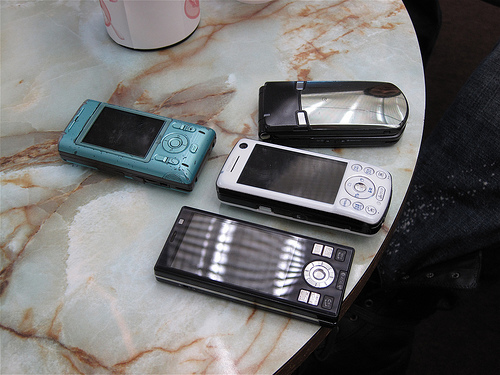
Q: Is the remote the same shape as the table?
A: Yes, both the remote and the table are round.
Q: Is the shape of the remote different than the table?
A: No, both the remote and the table are round.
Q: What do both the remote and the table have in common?
A: The shape, both the remote and the table are round.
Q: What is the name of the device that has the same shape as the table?
A: The device is a remote control.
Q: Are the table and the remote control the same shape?
A: Yes, both the table and the remote control are round.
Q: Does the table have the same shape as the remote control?
A: Yes, both the table and the remote control are round.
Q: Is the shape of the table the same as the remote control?
A: Yes, both the table and the remote control are round.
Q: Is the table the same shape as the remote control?
A: Yes, both the table and the remote control are round.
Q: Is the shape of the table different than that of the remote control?
A: No, both the table and the remote control are round.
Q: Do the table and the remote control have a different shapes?
A: No, both the table and the remote control are round.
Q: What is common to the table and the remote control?
A: The shape, both the table and the remote control are round.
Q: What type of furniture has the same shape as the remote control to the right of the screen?
A: The table is the same shape as the remote.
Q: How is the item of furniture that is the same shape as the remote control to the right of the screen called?
A: The piece of furniture is a table.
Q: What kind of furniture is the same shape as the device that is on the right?
A: The table is the same shape as the remote.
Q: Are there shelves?
A: No, there are no shelves.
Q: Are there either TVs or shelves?
A: No, there are no shelves or tvs.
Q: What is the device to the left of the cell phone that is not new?
A: The device is a screen.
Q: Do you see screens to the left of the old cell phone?
A: Yes, there is a screen to the left of the cellphone.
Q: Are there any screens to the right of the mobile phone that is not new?
A: No, the screen is to the left of the cell phone.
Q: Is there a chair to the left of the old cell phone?
A: No, there is a screen to the left of the cellphone.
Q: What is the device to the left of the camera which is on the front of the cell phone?
A: The device is a screen.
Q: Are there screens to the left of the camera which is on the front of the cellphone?
A: Yes, there is a screen to the left of the camera.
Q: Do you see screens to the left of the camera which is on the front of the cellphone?
A: Yes, there is a screen to the left of the camera.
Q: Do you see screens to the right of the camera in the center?
A: No, the screen is to the left of the camera.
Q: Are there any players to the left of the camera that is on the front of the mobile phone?
A: No, there is a screen to the left of the camera.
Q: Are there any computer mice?
A: No, there are no computer mice.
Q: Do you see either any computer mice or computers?
A: No, there are no computer mice or computers.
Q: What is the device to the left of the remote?
A: The device is a screen.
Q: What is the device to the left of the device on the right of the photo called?
A: The device is a screen.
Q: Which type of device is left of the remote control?
A: The device is a screen.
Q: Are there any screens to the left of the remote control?
A: Yes, there is a screen to the left of the remote control.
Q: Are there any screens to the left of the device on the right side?
A: Yes, there is a screen to the left of the remote control.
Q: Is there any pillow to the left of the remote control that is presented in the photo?
A: No, there is a screen to the left of the remote control.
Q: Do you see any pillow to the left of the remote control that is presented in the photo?
A: No, there is a screen to the left of the remote control.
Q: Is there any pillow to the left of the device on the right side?
A: No, there is a screen to the left of the remote control.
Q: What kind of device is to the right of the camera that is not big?
A: The device is a screen.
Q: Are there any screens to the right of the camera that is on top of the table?
A: Yes, there is a screen to the right of the camera.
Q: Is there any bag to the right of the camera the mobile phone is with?
A: No, there is a screen to the right of the camera.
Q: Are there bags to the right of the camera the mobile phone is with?
A: No, there is a screen to the right of the camera.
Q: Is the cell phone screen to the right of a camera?
A: Yes, the screen is to the right of a camera.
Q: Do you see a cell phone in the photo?
A: Yes, there is a cell phone.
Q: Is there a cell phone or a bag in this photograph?
A: Yes, there is a cell phone.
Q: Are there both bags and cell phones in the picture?
A: No, there is a cell phone but no bags.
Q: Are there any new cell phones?
A: Yes, there is a new cell phone.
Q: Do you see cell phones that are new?
A: Yes, there is a cell phone that is new.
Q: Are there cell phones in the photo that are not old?
A: Yes, there is an new cell phone.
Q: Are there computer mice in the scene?
A: No, there are no computer mice.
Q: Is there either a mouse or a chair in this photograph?
A: No, there are no computer mice or chairs.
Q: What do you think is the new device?
A: The device is a cell phone.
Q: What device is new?
A: The device is a cell phone.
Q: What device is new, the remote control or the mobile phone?
A: The mobile phone is new.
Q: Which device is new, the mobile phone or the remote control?
A: The mobile phone is new.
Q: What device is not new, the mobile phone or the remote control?
A: The remote control is not new.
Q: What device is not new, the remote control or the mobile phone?
A: The remote control is not new.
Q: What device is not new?
A: The device is a remote control.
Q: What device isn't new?
A: The device is a remote control.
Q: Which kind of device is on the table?
A: The device is a cell phone.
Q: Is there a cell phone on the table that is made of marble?
A: Yes, there is a cell phone on the table.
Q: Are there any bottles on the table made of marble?
A: No, there is a cell phone on the table.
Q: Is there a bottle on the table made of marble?
A: No, there is a cell phone on the table.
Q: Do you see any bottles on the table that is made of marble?
A: No, there is a cell phone on the table.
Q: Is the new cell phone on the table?
A: Yes, the mobile phone is on the table.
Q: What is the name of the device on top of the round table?
A: The device is a cell phone.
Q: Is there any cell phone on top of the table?
A: Yes, there is a cell phone on top of the table.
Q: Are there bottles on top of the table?
A: No, there is a cell phone on top of the table.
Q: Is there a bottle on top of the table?
A: No, there is a cell phone on top of the table.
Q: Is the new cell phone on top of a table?
A: Yes, the mobile phone is on top of a table.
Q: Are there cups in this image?
A: Yes, there is a cup.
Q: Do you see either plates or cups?
A: Yes, there is a cup.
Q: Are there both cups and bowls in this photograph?
A: No, there is a cup but no bowls.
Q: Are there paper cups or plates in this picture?
A: Yes, there is a paper cup.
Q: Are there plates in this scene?
A: No, there are no plates.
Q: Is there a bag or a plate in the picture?
A: No, there are no plates or bags.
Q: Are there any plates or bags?
A: No, there are no plates or bags.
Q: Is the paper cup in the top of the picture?
A: Yes, the cup is in the top of the image.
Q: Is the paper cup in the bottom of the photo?
A: No, the cup is in the top of the image.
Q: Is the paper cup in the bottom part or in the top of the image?
A: The cup is in the top of the image.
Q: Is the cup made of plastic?
A: No, the cup is made of paper.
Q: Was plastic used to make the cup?
A: No, the cup is made of paper.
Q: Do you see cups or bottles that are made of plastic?
A: No, there is a cup but it is made of paper.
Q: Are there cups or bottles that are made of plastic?
A: No, there is a cup but it is made of paper.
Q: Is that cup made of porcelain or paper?
A: The cup is made of paper.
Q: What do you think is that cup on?
A: The cup is on the table.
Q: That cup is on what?
A: The cup is on the table.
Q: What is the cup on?
A: The cup is on the table.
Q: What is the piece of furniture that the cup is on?
A: The piece of furniture is a table.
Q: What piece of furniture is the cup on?
A: The cup is on the table.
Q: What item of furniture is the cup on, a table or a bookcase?
A: The cup is on a table.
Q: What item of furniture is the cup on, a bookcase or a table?
A: The cup is on a table.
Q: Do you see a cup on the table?
A: Yes, there is a cup on the table.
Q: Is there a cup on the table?
A: Yes, there is a cup on the table.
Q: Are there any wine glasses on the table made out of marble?
A: No, there is a cup on the table.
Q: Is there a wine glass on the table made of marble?
A: No, there is a cup on the table.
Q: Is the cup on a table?
A: Yes, the cup is on a table.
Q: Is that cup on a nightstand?
A: No, the cup is on a table.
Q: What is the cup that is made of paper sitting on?
A: The cup is sitting on the table.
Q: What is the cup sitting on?
A: The cup is sitting on the table.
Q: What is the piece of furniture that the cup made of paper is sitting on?
A: The piece of furniture is a table.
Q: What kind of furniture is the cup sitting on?
A: The cup is sitting on the table.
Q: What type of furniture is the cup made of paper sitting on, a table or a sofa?
A: The cup is sitting on a table.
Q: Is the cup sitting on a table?
A: Yes, the cup is sitting on a table.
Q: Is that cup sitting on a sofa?
A: No, the cup is sitting on a table.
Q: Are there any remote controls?
A: Yes, there is a remote control.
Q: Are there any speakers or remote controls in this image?
A: Yes, there is a remote control.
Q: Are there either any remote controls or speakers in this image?
A: Yes, there is a remote control.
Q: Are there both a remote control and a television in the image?
A: No, there is a remote control but no televisions.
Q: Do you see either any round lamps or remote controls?
A: Yes, there is a round remote control.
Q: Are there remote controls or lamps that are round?
A: Yes, the remote control is round.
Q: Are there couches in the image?
A: No, there are no couches.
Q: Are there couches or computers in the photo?
A: No, there are no couches or computers.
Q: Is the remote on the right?
A: Yes, the remote is on the right of the image.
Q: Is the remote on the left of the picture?
A: No, the remote is on the right of the image.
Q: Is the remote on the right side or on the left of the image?
A: The remote is on the right of the image.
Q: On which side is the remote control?
A: The remote control is on the right of the image.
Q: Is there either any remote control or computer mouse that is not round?
A: No, there is a remote control but it is round.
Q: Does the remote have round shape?
A: Yes, the remote is round.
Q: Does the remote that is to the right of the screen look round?
A: Yes, the remote control is round.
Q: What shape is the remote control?
A: The remote control is round.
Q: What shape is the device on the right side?
A: The remote control is round.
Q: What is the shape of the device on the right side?
A: The remote control is round.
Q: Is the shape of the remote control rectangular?
A: No, the remote control is round.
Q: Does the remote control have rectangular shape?
A: No, the remote control is round.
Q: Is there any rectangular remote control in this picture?
A: No, there is a remote control but it is round.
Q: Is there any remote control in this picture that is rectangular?
A: No, there is a remote control but it is round.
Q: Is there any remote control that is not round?
A: No, there is a remote control but it is round.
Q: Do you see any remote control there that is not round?
A: No, there is a remote control but it is round.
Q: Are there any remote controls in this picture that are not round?
A: No, there is a remote control but it is round.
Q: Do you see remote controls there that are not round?
A: No, there is a remote control but it is round.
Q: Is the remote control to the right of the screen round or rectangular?
A: The remote is round.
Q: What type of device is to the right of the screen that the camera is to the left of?
A: The device is a remote control.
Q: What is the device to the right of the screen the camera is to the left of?
A: The device is a remote control.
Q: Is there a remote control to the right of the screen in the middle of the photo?
A: Yes, there is a remote control to the right of the screen.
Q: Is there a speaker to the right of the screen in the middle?
A: No, there is a remote control to the right of the screen.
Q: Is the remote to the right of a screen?
A: Yes, the remote is to the right of a screen.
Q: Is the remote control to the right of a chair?
A: No, the remote control is to the right of a screen.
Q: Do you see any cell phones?
A: Yes, there is a cell phone.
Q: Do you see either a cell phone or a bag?
A: Yes, there is a cell phone.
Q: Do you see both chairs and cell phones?
A: No, there is a cell phone but no chairs.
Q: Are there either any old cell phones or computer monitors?
A: Yes, there is an old cell phone.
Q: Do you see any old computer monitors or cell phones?
A: Yes, there is an old cell phone.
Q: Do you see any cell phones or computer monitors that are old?
A: Yes, the cell phone is old.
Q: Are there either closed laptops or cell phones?
A: Yes, there is a closed cell phone.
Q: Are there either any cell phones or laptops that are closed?
A: Yes, the cell phone is closed.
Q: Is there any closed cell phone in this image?
A: Yes, there is a closed cell phone.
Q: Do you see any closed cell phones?
A: Yes, there is a closed cell phone.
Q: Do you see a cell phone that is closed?
A: Yes, there is a cell phone that is closed.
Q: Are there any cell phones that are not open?
A: Yes, there is an closed cell phone.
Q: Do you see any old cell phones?
A: Yes, there is an old cell phone.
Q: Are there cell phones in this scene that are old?
A: Yes, there is a cell phone that is old.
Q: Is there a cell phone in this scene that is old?
A: Yes, there is a cell phone that is old.